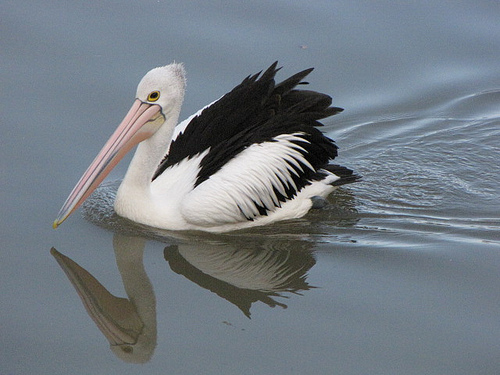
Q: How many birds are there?
A: 1.